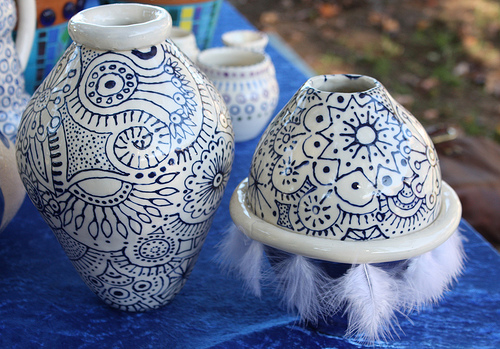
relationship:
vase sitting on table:
[227, 73, 463, 323] [1, 0, 495, 345]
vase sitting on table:
[14, 3, 235, 314] [1, 0, 495, 345]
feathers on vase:
[218, 224, 465, 343] [231, 71, 464, 264]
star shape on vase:
[315, 100, 409, 187] [227, 73, 463, 323]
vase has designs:
[14, 3, 235, 314] [61, 113, 189, 269]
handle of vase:
[11, 0, 41, 67] [3, 1, 30, 227]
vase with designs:
[232, 71, 477, 281] [299, 98, 406, 231]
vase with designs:
[192, 36, 290, 145] [236, 83, 267, 116]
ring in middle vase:
[225, 178, 463, 266] [227, 73, 463, 323]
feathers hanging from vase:
[218, 224, 465, 343] [227, 73, 463, 323]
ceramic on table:
[228, 62, 468, 342] [1, 0, 495, 345]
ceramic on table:
[19, 4, 234, 311] [1, 0, 495, 345]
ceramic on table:
[194, 47, 279, 142] [1, 0, 495, 345]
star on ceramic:
[294, 89, 442, 216] [228, 62, 468, 342]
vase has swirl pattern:
[13, 3, 235, 327] [76, 54, 173, 151]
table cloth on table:
[0, 0, 495, 342] [1, 0, 495, 345]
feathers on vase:
[218, 224, 465, 343] [238, 68, 463, 283]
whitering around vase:
[227, 174, 471, 264] [227, 73, 463, 323]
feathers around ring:
[300, 243, 459, 332] [225, 178, 463, 266]